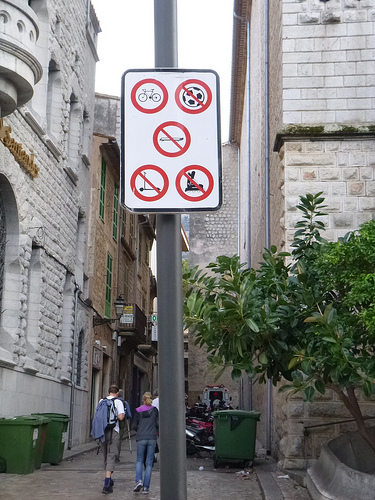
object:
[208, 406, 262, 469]
dumpster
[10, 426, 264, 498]
alley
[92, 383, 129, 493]
person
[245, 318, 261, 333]
leaf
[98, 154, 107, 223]
shutter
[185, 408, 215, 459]
bike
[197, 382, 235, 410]
vehicle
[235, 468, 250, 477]
litter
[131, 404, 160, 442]
hoodie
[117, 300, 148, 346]
balcony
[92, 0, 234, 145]
sky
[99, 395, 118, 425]
backpack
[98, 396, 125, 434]
shirt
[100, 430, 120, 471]
capris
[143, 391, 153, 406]
hair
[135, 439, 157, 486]
jeans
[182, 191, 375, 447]
tree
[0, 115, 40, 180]
writing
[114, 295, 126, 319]
light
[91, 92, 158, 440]
building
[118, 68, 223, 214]
sign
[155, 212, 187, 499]
pole